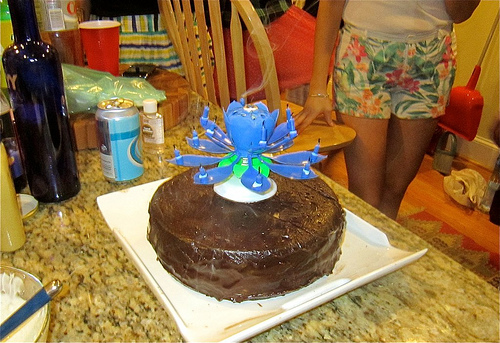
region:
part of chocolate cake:
[162, 215, 268, 264]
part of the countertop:
[372, 290, 451, 336]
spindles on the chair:
[172, 12, 270, 64]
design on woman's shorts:
[357, 50, 437, 92]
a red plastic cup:
[82, 22, 120, 65]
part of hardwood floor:
[422, 190, 444, 211]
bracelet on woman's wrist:
[302, 92, 330, 99]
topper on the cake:
[181, 108, 326, 193]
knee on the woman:
[355, 177, 379, 201]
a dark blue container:
[2, 52, 70, 193]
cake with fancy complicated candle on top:
[97, 95, 426, 325]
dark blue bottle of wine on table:
[4, 3, 89, 205]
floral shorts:
[323, 16, 461, 132]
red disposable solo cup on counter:
[70, 14, 130, 97]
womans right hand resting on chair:
[285, 69, 350, 155]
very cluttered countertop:
[0, 30, 497, 335]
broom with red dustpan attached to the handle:
[426, 5, 497, 179]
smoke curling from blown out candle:
[232, 2, 294, 120]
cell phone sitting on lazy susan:
[124, 50, 161, 90]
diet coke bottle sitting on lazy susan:
[36, 0, 98, 72]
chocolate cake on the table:
[165, 116, 330, 286]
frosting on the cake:
[199, 230, 269, 285]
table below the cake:
[394, 284, 451, 317]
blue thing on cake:
[203, 86, 294, 193]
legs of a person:
[336, 122, 446, 196]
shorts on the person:
[336, 23, 458, 126]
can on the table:
[91, 83, 161, 177]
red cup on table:
[68, 18, 130, 81]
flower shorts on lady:
[326, 38, 466, 140]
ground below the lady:
[438, 218, 476, 246]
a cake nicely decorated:
[137, 89, 358, 303]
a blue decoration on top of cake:
[153, 93, 337, 200]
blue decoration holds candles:
[162, 84, 339, 201]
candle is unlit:
[239, 156, 278, 203]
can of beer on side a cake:
[91, 90, 150, 190]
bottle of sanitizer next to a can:
[134, 91, 174, 171]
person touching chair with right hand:
[299, 1, 485, 221]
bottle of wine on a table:
[0, 0, 88, 208]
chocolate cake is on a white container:
[142, 159, 352, 310]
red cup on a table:
[69, 14, 130, 79]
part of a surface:
[411, 287, 435, 307]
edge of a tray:
[327, 280, 370, 311]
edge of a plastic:
[233, 198, 262, 208]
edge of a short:
[405, 102, 440, 132]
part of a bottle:
[46, 107, 74, 152]